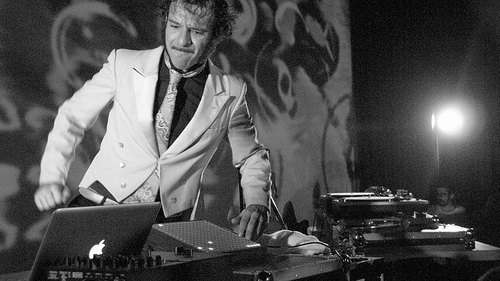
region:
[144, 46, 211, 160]
tie around a man's neck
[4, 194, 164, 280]
laptop computer with logo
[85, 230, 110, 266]
white logo on laptop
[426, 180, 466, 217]
person sitting in background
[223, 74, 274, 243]
arm of a person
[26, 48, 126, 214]
arm of a person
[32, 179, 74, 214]
hand of a person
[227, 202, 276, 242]
hand of a person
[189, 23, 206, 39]
eye of a person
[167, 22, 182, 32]
eye of a person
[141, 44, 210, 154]
tie around someone's neck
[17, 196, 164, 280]
laptop computer on a desk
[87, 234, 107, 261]
logo on a laptop computer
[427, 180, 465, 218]
person sitting in the background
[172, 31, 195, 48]
nose of a person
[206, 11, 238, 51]
Man has dark hair.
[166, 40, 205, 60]
Man has dark mustache.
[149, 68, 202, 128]
Man wearing tie around neck.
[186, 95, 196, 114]
Man wearing black shirt.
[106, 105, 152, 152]
Man wearing light colored jacket.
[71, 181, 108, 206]
Man wearing gray belt.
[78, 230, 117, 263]
Apple logo on computer.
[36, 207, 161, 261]
Silver laptop on table.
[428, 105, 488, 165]
Bright light in background.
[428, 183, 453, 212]
Person sitting under light.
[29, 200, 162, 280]
Open Apple laptop computer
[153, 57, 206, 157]
Long men's neck tie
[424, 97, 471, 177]
Standing round light pole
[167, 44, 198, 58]
Long black man's mustache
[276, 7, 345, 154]
Black and white print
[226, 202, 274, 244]
Left white male's hand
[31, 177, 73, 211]
Right close fist white male's hand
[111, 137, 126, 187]
Man's lined buttons on coat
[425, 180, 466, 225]
Man with mustache sitting down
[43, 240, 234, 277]
Electronic equipment with many buttons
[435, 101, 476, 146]
The round light in the background.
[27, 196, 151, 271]
Silver Apple laptop computer.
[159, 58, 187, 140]
Tie around the mans neck.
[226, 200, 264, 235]
The mans left hand.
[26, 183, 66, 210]
The mans right hand.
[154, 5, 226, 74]
The mans head.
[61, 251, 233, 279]
Black mixing equipment.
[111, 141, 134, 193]
Three round buttons.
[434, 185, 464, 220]
Man sitting down on the right.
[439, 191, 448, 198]
Pair of glasses.